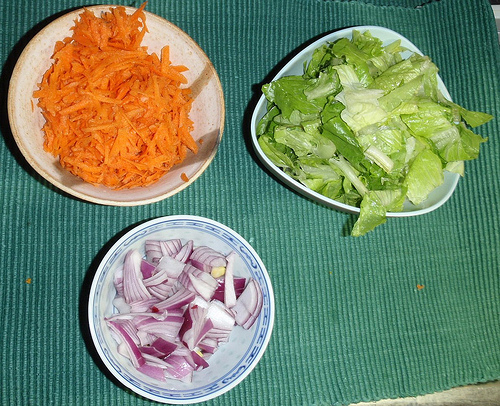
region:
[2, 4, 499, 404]
three plates of food ingredients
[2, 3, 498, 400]
three plates of food on a blue tablecloth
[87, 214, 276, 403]
plate of chopped red onion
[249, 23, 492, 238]
plate of chopped lettus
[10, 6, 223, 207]
plate of shredded carrots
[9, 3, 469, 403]
trio of ingredients on plates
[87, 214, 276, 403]
chopped onion on blue and white round plate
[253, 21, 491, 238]
chopped lettuce on a rounded triangular white plate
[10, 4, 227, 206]
shredded carrots on white plate with brown pattern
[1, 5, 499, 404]
woven turquoise tablecloth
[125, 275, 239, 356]
red onions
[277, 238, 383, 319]
a green cloth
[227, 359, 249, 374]
rim of the plate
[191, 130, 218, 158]
shadow on the plate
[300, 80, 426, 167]
green lettuce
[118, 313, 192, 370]
onions on the plate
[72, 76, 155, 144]
orange vegetables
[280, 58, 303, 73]
a white bowl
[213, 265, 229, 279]
an object in the plate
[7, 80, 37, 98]
the plate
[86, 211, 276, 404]
bowl of chopped red onions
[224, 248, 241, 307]
piece of red onion in a blue and white bowl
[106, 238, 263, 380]
lots of chopped pieces of red onions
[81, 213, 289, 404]
bowl of chopped red onions on a green placemat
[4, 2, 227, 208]
tan and white bowl of shredded carrots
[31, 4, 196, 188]
pile of shredded carrots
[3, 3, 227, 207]
bowl of shredded carrots on a green placemat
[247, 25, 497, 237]
small bowl of chopped mixed lettuce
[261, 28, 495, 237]
pile of green lettuce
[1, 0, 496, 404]
three small bowls of food on a placemat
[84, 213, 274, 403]
A plate of red onions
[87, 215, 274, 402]
A plate of chopped onions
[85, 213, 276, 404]
A white plate with blue trim full of onions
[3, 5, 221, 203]
A plate of shredded cheese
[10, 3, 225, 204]
A plate of cheddar cheese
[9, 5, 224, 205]
A white plate of shredded cheddar cheese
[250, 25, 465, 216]
A white bowl with lettuce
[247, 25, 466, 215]
A white bowl with torn lettuce leaves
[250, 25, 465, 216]
A white bowl with pieces of Iceberg lettuce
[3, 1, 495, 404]
A table with plates of food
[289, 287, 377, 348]
the cloth is green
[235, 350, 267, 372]
a plate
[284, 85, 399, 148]
the lettuce is green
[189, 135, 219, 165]
a shadow on the plate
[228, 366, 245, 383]
the rim of the plate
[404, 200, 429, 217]
a white bowl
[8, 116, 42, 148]
the plate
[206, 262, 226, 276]
an object on the plate